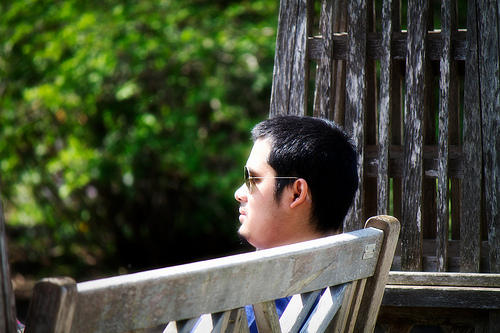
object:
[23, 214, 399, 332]
bench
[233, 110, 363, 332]
man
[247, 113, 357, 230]
hair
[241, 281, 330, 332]
shirt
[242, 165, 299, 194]
sunglasses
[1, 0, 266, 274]
trees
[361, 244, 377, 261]
marking tag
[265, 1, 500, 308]
fence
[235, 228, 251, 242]
goattee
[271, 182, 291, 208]
sideburns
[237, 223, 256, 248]
chin